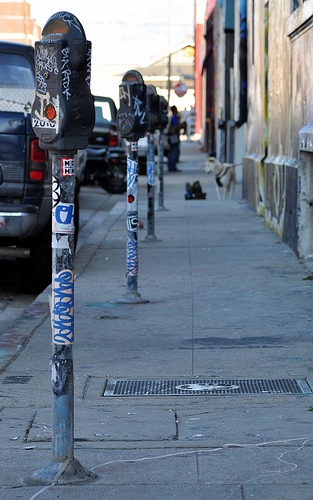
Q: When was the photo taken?
A: Day time.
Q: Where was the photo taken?
A: On a city street.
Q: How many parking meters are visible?
A: Four.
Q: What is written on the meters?
A: Graffiti.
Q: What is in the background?
A: Sunlight.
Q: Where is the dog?
A: On the sidewalk.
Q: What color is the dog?
A: White.